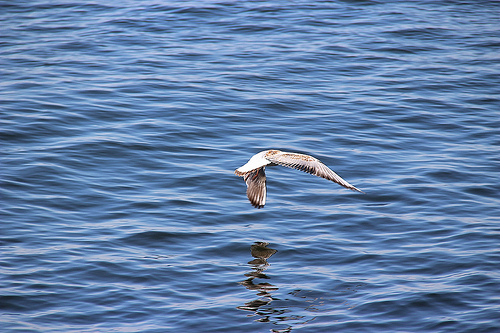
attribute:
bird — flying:
[206, 113, 371, 222]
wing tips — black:
[278, 158, 328, 182]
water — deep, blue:
[56, 28, 257, 159]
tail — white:
[238, 157, 268, 169]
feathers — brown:
[234, 169, 263, 177]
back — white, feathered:
[256, 150, 272, 162]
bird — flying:
[230, 119, 350, 209]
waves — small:
[1, 1, 496, 330]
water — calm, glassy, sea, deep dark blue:
[7, 8, 491, 330]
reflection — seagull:
[236, 237, 306, 331]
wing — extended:
[267, 147, 378, 209]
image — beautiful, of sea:
[4, 1, 498, 328]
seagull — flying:
[232, 144, 364, 200]